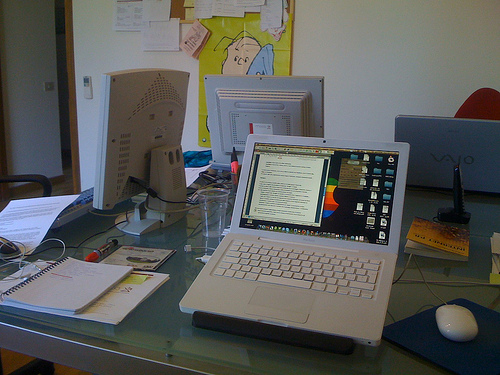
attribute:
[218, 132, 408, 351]
laptop — white, open, small, in foreground, on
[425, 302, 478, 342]
mouse — white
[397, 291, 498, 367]
mousepad — blue, in foreground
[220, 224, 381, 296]
keyboard — white, grey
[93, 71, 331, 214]
monitors — white, stand-up, in background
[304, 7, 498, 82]
wall — white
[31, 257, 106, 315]
notebook — white, in foreground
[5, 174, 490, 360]
table — blue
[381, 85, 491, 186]
laptop — grey, silver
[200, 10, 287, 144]
poster — green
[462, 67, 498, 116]
chair — red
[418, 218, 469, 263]
cover — orange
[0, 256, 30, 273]
mousepad — black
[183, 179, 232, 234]
glass — plastic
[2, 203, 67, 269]
paper — white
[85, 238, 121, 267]
marker — red